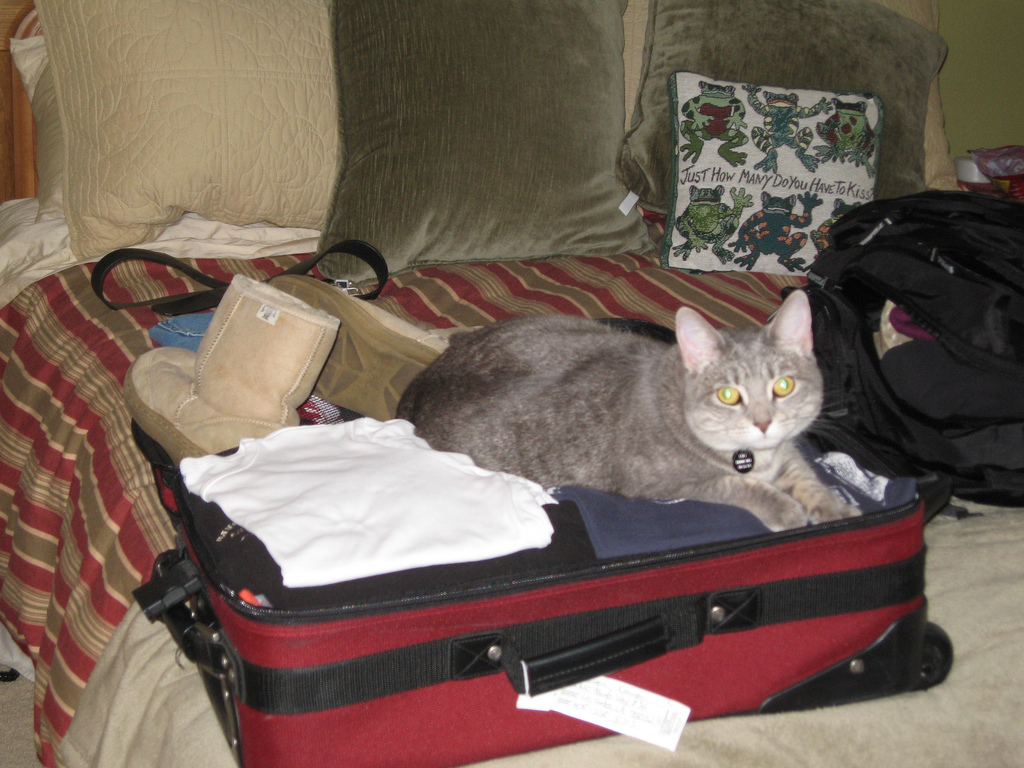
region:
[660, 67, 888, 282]
Small throw pillow with frogs and lettering on it.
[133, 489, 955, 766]
Red suitcase laying opened on bed.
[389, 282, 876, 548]
Gray cat laying on top of suitcase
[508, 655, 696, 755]
Paper tag on handle of suitcase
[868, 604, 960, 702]
Black plastic wheel on suitcase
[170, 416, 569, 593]
White shirt packed on top of suitcase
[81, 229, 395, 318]
Folded, black leather belt.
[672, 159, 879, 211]
Lettering on throwpillow which reads "Just how many do you have to kiss"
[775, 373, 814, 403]
eye of the cat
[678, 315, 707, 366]
ear of the cat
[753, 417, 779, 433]
nose of the cat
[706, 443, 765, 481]
tag on the collar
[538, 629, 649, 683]
handle on the suitcase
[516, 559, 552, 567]
shirt in the suitcase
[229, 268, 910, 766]
gray cat sitting in a suitcase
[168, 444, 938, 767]
red suitcase with clothes in it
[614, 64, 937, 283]
pillow with frogs on it sitting on the bed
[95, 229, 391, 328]
black belt laying on a bed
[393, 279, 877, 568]
gray cat laying on a pile of clothes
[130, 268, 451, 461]
tan boots sitting on a bed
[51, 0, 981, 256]
4 pillows sitting on a bed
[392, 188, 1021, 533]
gray cat laying by black duffel bag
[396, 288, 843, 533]
Grey cat is laying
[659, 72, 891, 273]
White pillow with frogs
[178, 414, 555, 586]
White shirt in the luggage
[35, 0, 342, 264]
Light brown pillow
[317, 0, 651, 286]
Dark brown pillow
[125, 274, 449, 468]
the uggs are beige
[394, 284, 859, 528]
the cat is gray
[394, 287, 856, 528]
the cat is lying down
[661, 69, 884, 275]
the frogs on the pillow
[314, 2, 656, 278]
the pillow is green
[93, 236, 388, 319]
the belt is black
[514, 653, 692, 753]
the luggage tag is white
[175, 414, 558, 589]
the folded white shirt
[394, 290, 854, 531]
the cat has green eyes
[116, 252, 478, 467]
a pair of short boots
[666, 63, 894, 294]
a pillow with 6 frogs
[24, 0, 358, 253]
a throw pillow with patterns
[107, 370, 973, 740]
a red suitcase with clothes and a cat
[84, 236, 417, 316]
a black leather belt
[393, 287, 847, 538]
fluffy grey cat laying down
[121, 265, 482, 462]
beige boots with brown soles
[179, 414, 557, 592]
neatly folded white shirt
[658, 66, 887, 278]
white and green pillow with frogs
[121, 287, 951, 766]
cat laying inside of a red and black suitcase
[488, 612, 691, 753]
white tag hanging off black handle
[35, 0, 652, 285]
beige pillow next to green pillow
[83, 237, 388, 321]
black belt laying on comforter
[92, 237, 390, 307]
a black belt on a bed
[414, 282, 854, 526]
a grey cat on a suitcase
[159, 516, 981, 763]
a red and black suitcase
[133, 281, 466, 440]
a pair of tan boots on a bed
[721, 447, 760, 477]
a black tag on a cat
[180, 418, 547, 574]
a folded white shirt on a suitcase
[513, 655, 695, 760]
a white paper tag on a suitcase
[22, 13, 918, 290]
several pillows on a bed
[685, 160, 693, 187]
A letter on a pillow.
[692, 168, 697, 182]
A letter on a pillow.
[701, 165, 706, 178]
A letter on a pillow.